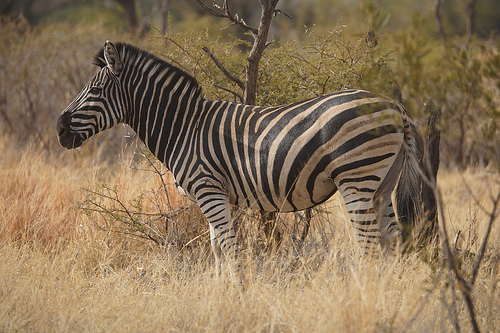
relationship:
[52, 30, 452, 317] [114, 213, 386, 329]
zebra standing in grass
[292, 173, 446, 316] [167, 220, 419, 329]
legs hidden by grass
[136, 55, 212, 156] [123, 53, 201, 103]
stripes extending into mane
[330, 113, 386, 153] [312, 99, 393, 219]
lines between stripes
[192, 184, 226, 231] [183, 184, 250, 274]
lines across leg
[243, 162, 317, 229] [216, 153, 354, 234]
stipes under belly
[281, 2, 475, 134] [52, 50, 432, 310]
tree on side of zebra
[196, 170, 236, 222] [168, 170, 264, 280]
stripes on zebra's legs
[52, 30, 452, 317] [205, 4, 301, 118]
zebra standing in front of tree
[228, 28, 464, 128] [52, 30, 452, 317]
bushes behind zebra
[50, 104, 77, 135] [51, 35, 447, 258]
nose on zebra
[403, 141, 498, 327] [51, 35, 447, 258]
twigs are in front of zebra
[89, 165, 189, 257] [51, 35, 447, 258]
branches reaching out toward zebra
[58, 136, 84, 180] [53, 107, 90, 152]
grass hanging from mouth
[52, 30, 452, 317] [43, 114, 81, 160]
zebra has nose